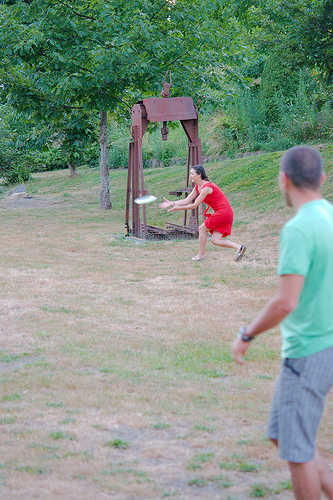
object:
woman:
[159, 164, 247, 262]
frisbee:
[134, 193, 158, 208]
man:
[232, 145, 333, 498]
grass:
[0, 326, 332, 496]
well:
[124, 68, 206, 240]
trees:
[275, 23, 333, 149]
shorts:
[265, 345, 332, 464]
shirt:
[277, 198, 332, 357]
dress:
[194, 180, 233, 236]